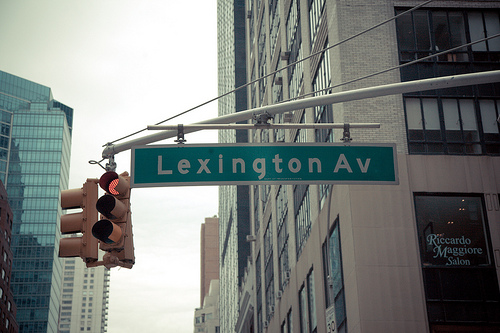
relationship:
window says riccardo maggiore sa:
[416, 192, 498, 321] [428, 233, 482, 264]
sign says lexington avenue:
[131, 143, 400, 186] [156, 154, 371, 173]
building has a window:
[242, 2, 499, 330] [416, 192, 498, 321]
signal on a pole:
[92, 170, 135, 269] [102, 67, 495, 159]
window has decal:
[416, 192, 498, 321] [428, 232, 484, 265]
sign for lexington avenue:
[131, 143, 400, 186] [156, 154, 371, 173]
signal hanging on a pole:
[92, 170, 135, 269] [102, 67, 495, 159]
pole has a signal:
[102, 67, 495, 159] [92, 170, 135, 269]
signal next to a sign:
[92, 170, 135, 269] [131, 143, 400, 186]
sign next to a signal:
[131, 143, 400, 186] [92, 170, 135, 269]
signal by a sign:
[92, 170, 135, 269] [131, 143, 400, 186]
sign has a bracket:
[131, 143, 400, 186] [178, 138, 189, 144]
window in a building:
[416, 192, 498, 321] [242, 2, 499, 330]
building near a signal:
[242, 2, 499, 330] [92, 170, 135, 269]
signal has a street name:
[92, 170, 135, 269] [157, 154, 370, 173]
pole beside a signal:
[102, 67, 495, 159] [92, 170, 135, 269]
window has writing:
[416, 192, 498, 321] [157, 155, 171, 175]